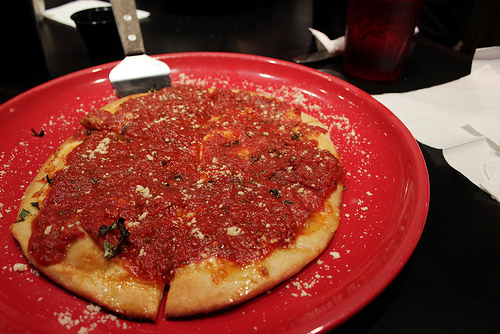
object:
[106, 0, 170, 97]
pizza spatula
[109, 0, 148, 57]
handle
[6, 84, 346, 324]
pizza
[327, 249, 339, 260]
parmesan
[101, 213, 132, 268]
basil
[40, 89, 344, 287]
marinara sauce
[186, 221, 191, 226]
spices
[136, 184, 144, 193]
spices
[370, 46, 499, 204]
cloth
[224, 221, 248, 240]
cheese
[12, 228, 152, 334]
crust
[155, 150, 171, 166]
seasoning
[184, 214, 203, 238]
cheese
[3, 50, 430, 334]
plate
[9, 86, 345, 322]
surface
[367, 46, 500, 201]
napkin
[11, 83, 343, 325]
pie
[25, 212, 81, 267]
tomatoes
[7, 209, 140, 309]
crust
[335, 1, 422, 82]
plastic cup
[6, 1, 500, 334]
table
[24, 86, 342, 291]
tomato paste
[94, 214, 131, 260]
herb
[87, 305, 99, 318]
parmesan cheese